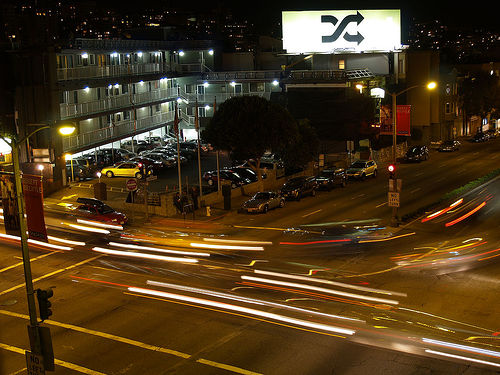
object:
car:
[101, 159, 153, 179]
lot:
[48, 134, 326, 212]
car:
[141, 152, 176, 169]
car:
[201, 168, 251, 189]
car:
[240, 190, 287, 216]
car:
[344, 158, 379, 182]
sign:
[278, 6, 404, 56]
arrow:
[316, 9, 365, 47]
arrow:
[340, 30, 365, 46]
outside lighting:
[81, 52, 90, 59]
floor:
[47, 49, 215, 83]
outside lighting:
[82, 86, 92, 95]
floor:
[53, 75, 200, 122]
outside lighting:
[228, 81, 240, 88]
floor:
[178, 77, 282, 105]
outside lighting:
[85, 117, 94, 124]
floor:
[56, 97, 178, 156]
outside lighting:
[203, 104, 212, 111]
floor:
[177, 98, 220, 127]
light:
[76, 217, 124, 231]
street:
[1, 128, 500, 374]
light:
[188, 240, 265, 251]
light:
[106, 240, 210, 258]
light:
[253, 268, 408, 299]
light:
[47, 234, 87, 247]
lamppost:
[5, 135, 44, 356]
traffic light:
[36, 287, 55, 322]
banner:
[21, 173, 52, 246]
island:
[372, 167, 500, 236]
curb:
[201, 130, 499, 220]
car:
[314, 165, 348, 193]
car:
[402, 143, 431, 164]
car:
[436, 139, 462, 154]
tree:
[199, 93, 302, 196]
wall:
[196, 156, 317, 208]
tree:
[272, 115, 323, 173]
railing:
[55, 60, 164, 85]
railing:
[58, 85, 181, 123]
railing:
[178, 86, 272, 104]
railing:
[61, 109, 177, 155]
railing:
[179, 108, 197, 127]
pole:
[174, 100, 183, 199]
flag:
[174, 102, 180, 137]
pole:
[195, 96, 204, 202]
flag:
[194, 97, 201, 132]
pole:
[214, 94, 222, 193]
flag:
[213, 96, 217, 114]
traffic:
[1, 178, 500, 368]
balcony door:
[82, 57, 89, 67]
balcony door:
[96, 86, 102, 101]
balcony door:
[75, 121, 81, 135]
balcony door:
[233, 83, 243, 94]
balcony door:
[197, 106, 206, 117]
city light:
[420, 30, 424, 34]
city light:
[144, 22, 160, 27]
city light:
[97, 33, 103, 38]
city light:
[42, 12, 47, 17]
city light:
[435, 19, 440, 24]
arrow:
[59, 193, 78, 203]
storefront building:
[435, 61, 462, 145]